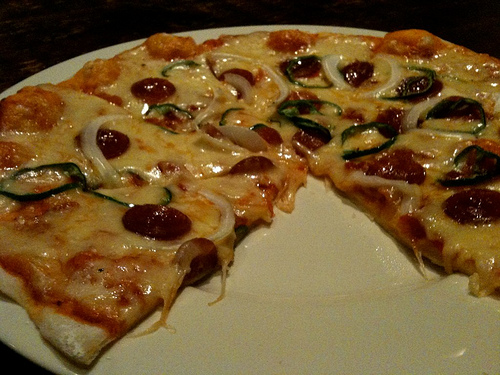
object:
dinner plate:
[0, 23, 499, 374]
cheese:
[0, 30, 499, 373]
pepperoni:
[294, 131, 317, 153]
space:
[102, 175, 498, 375]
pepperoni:
[252, 123, 284, 145]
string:
[0, 160, 89, 200]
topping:
[120, 202, 195, 240]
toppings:
[376, 97, 488, 134]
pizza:
[0, 26, 500, 373]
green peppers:
[3, 72, 483, 212]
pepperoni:
[347, 150, 420, 181]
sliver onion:
[321, 50, 376, 92]